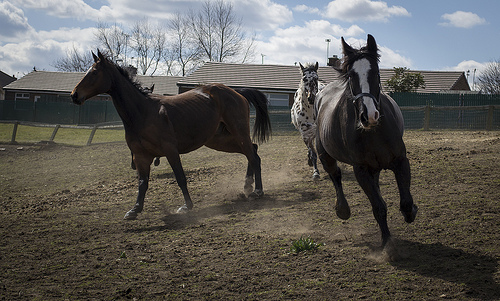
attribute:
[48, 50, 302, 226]
horse — brown, white, running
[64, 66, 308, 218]
horse — running, white, brown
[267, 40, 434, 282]
horse — brown, white, running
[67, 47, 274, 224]
horse — running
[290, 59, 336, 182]
horse — running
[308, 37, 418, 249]
horse — running, white, brown